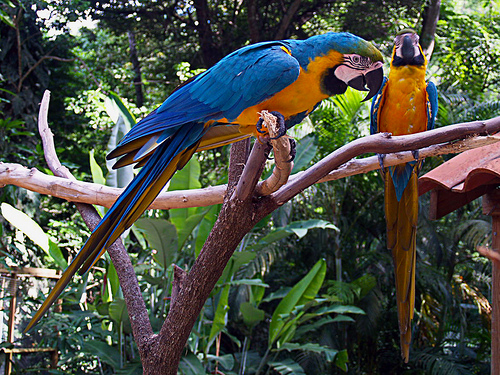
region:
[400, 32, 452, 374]
This parrot is yellow and blue in color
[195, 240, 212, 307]
This tree has dark brown bark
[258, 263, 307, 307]
There are green plants that are in the photo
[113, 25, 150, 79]
There are dark green trees int he distance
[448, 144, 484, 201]
There is a red roof that is int he photo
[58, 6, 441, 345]
Jackson Mingus took this photo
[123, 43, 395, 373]
This photo was taken in the country of Jamaica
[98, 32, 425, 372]
Allen Steinberg paid for the rights to this photo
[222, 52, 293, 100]
blue feathers on a bird's shoulder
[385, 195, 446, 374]
long yellow tail feathers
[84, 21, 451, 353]
two giant macaws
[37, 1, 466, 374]
two big birds on branches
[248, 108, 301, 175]
talons holding onto a branch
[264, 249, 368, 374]
green lush foliage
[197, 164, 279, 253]
wooden bird perch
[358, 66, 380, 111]
black beak on a parrott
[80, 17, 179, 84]
trees lining the background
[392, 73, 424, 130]
yellow belly of a bird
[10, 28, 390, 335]
Parrot perched on wooden branch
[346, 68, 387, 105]
Black beak on parrot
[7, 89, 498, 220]
Wooden perch for parrots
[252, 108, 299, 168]
Parrot claws gripping wooden perch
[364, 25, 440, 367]
Front view of perched parrot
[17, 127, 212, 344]
Blue and yellow tail of parrot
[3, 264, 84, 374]
Wooden and metal bird enclosure fence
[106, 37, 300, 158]
Parrot wing with blue feathers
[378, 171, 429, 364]
Yellow tail feathers of parrot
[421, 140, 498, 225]
Wooden roof of parrot house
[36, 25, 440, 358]
Two birds sitting on branches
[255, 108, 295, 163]
Blue bird's feet wrapped about branch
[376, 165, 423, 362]
Long yellow tail of bird facing camera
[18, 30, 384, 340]
Blue and Yellow bird facing right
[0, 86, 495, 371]
Tree branch with two birds on it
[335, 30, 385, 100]
Black and white face of bird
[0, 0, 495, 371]
Beautiful and vibrant green vegetation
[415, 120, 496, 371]
Roof and unknown structure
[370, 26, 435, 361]
Blue and yellow bird facing camera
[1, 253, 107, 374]
Unknown wood structure behind leaves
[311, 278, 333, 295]
part of a leaf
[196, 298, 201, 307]
part of a branch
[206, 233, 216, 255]
part of a tree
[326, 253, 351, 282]
part of a vegetation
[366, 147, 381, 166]
part of a twig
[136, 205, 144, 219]
part of a bird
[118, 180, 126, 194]
tail of a bird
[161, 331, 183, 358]
edge of a tree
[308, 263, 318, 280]
tip of a leaf